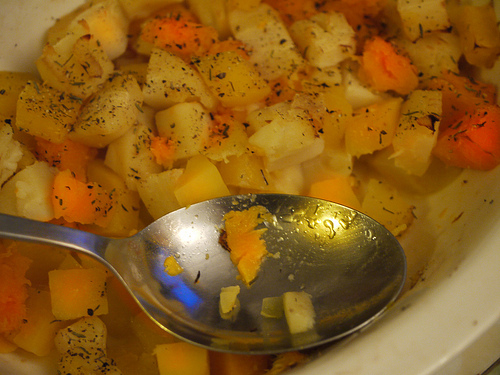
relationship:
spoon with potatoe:
[0, 191, 407, 355] [347, 98, 400, 160]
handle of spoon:
[0, 209, 103, 262] [0, 191, 407, 355]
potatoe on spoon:
[347, 98, 400, 160] [0, 191, 407, 355]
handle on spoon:
[0, 209, 103, 262] [0, 191, 407, 355]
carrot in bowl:
[439, 102, 499, 168] [4, 1, 500, 374]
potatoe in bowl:
[347, 98, 400, 160] [4, 1, 500, 374]